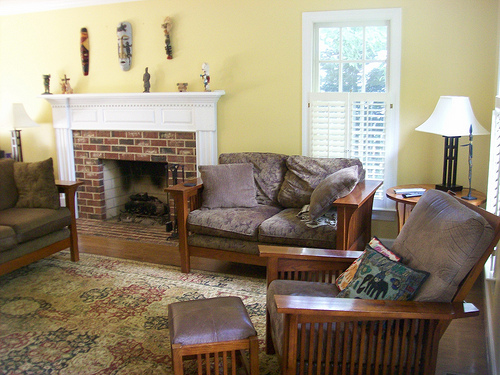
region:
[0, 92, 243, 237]
brick fireplace with white mantle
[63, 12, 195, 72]
multi colored decorations on wall above fireplace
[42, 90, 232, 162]
white wooden mantle around fire place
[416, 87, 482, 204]
white lamp shade on black stand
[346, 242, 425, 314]
colorful pillow with elephant design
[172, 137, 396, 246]
light brown suede and wood loveseat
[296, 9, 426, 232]
white window casing around glass window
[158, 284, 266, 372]
wood and suede foot stool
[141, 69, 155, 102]
small grey statue on mantle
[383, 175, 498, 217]
round wooden end table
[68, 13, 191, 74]
decorations on a yellow wall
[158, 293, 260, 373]
a wood and leather ottoman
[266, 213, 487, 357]
a wood and leather rocking recliner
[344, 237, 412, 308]
a pillow with an image of an elephant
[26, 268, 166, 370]
an ornate area rug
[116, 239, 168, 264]
brown hardwood flooring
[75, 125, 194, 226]
a red and brown brich fireplace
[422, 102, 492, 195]
a black and white lamp on a table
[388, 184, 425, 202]
two remote controls on a table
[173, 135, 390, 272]
a two seater couch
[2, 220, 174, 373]
a large rug covering the floor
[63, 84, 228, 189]
a brick fire place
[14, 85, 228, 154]
a white fire place mantle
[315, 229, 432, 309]
two pillows on a chair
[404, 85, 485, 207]
a lamp on a wood table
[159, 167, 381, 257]
a wooden love seat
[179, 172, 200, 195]
a remote control on a couch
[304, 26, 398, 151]
a window partially covered by a wood shutter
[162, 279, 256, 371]
a wooden foot stool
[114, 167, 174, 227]
burned fire wood in a fire place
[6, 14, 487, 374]
Living room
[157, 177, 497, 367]
Brown chair and ottoman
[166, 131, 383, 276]
Couch with two pillows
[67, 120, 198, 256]
Brick fireplace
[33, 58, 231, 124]
Mantel with several figures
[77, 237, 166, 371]
Ornamental rug on a wood floor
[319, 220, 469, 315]
Two pillows on a chair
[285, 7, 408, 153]
Window with white shutters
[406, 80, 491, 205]
Lamp with white lampshade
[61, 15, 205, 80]
Decorations hanging on a yellow wall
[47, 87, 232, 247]
The fireplace is not lit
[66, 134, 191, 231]
There is no fire in the fireplace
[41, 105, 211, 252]
The fireplace has a brick front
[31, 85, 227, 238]
The fireplace mantle is white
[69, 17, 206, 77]
Decorations hanging on the wall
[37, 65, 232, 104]
Decorations sitting on the mantle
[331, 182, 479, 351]
The chair has 2 pillows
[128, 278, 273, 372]
The footstool has a leather top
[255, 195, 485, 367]
The chair arms are wood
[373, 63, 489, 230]
Table lamp has a white shade